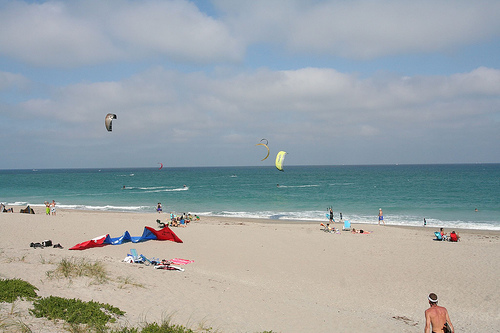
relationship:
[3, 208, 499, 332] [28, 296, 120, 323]
floor covered with green plants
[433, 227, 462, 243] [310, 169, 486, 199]
people watching sea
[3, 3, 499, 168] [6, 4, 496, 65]
sky covered with clouds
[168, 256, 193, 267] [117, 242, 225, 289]
towel laying on sand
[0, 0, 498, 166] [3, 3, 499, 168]
clouds in sky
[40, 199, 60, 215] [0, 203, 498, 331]
two people standing on sand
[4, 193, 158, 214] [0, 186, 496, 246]
waves rolling into shore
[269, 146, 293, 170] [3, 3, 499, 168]
kite in sky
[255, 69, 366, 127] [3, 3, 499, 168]
puffy clouds in sky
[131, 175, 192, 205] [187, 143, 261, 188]
waves on water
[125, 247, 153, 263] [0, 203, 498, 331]
chair on sand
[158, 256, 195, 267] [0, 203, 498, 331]
chair on sand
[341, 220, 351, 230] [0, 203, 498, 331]
chair on sand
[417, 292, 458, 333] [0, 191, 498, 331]
man in beach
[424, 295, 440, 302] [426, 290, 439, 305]
band on head